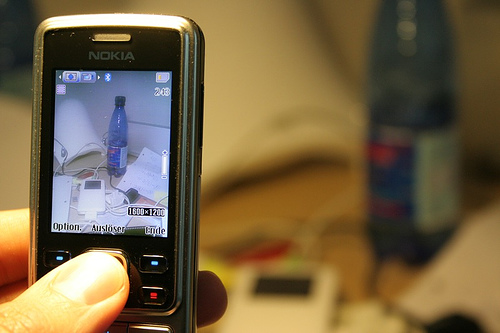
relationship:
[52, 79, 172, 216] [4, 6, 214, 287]
screen of phone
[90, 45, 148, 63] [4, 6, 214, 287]
brand of phone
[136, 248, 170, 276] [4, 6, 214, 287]
button on phone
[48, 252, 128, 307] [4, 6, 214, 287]
finger on phone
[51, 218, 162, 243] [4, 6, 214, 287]
option on phone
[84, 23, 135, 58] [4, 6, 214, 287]
speaker on phone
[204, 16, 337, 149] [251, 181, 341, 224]
book on bed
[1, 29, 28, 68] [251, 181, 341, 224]
pillow on bed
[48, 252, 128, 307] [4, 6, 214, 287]
finger behind phone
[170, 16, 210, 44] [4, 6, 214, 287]
edge of phone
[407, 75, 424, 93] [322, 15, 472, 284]
part of bottle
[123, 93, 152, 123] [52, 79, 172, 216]
part of camera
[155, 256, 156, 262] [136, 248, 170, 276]
part of button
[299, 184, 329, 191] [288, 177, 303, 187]
part of table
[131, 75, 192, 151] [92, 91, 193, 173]
part of gadget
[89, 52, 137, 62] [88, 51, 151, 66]
brand of compan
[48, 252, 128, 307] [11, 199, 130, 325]
finger of person